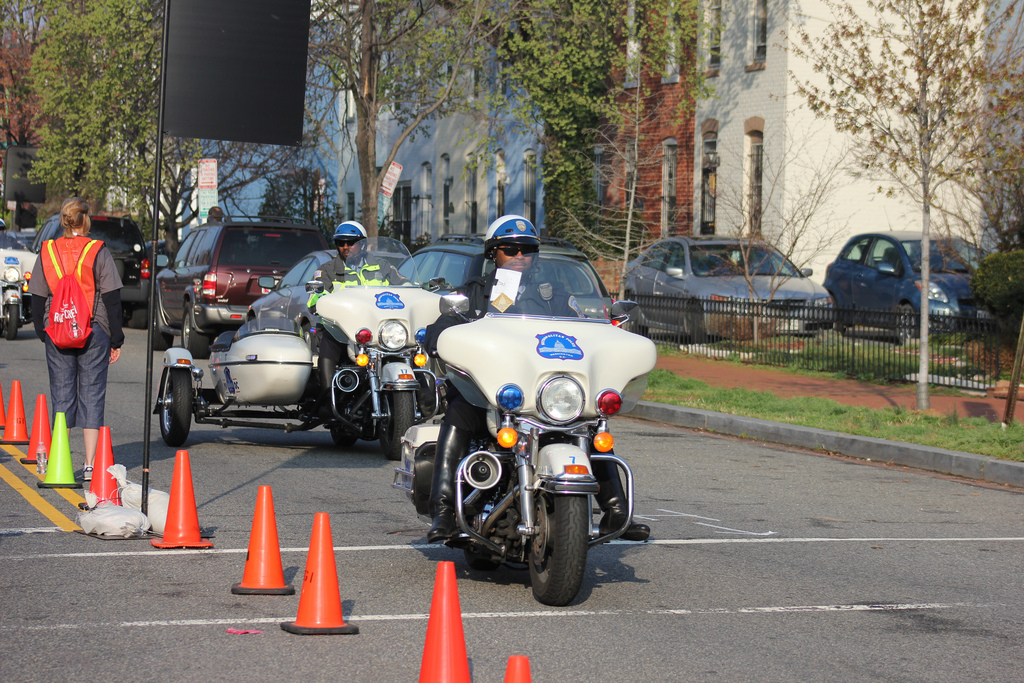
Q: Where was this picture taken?
A: On a city street.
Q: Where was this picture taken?
A: On the street.